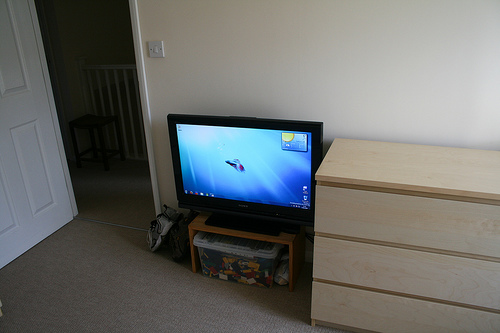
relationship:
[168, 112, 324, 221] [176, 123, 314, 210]
tv has screen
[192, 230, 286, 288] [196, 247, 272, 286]
container of legos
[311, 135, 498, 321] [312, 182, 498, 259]
dresser has drawer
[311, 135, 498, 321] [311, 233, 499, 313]
dresser has drawer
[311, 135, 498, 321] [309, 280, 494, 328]
dresser has drawer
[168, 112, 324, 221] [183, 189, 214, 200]
television has icons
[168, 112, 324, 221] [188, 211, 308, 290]
tv on table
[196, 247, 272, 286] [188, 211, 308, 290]
toys under table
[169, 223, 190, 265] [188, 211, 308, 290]
shoe next to table